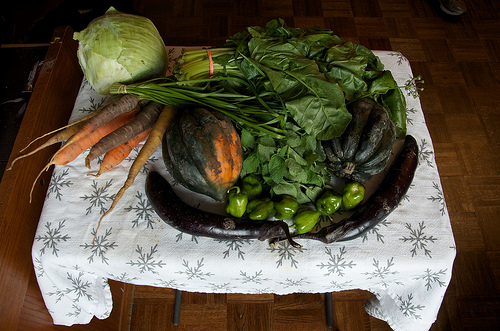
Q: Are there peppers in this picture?
A: Yes, there are peppers.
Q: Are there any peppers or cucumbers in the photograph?
A: Yes, there are peppers.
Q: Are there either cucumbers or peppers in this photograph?
A: Yes, there are peppers.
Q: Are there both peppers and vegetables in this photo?
A: Yes, there are both peppers and vegetables.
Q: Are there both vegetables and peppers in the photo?
A: Yes, there are both peppers and vegetables.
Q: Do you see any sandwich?
A: No, there are no sandwiches.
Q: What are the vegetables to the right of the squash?
A: The vegetables are peppers.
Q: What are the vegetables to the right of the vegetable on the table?
A: The vegetables are peppers.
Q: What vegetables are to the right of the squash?
A: The vegetables are peppers.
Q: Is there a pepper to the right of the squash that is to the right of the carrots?
A: Yes, there are peppers to the right of the squash.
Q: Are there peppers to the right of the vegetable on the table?
A: Yes, there are peppers to the right of the squash.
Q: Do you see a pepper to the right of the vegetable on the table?
A: Yes, there are peppers to the right of the squash.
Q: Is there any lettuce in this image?
A: Yes, there is lettuce.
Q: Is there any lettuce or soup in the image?
A: Yes, there is lettuce.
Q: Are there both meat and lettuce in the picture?
A: No, there is lettuce but no meat.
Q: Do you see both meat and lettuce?
A: No, there is lettuce but no meat.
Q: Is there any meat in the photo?
A: No, there is no meat.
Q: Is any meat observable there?
A: No, there is no meat.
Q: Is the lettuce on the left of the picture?
A: Yes, the lettuce is on the left of the image.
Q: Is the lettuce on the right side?
A: No, the lettuce is on the left of the image.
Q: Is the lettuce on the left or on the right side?
A: The lettuce is on the left of the image.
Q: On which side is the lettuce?
A: The lettuce is on the left of the image.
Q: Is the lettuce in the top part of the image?
A: Yes, the lettuce is in the top of the image.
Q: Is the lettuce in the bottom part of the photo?
A: No, the lettuce is in the top of the image.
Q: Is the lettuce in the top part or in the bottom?
A: The lettuce is in the top of the image.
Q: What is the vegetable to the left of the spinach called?
A: The vegetable is lettuce.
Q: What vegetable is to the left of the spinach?
A: The vegetable is lettuce.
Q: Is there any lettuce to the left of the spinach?
A: Yes, there is lettuce to the left of the spinach.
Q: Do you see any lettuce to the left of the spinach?
A: Yes, there is lettuce to the left of the spinach.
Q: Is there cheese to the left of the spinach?
A: No, there is lettuce to the left of the spinach.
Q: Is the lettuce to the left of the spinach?
A: Yes, the lettuce is to the left of the spinach.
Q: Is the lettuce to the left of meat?
A: No, the lettuce is to the left of the spinach.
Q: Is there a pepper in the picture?
A: Yes, there is a pepper.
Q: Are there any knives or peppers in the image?
A: Yes, there is a pepper.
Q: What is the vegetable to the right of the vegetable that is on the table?
A: The vegetable is a pepper.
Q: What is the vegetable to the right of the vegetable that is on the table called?
A: The vegetable is a pepper.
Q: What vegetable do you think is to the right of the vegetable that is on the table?
A: The vegetable is a pepper.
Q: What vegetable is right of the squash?
A: The vegetable is a pepper.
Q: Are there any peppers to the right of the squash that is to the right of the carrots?
A: Yes, there is a pepper to the right of the squash.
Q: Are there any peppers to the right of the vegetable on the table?
A: Yes, there is a pepper to the right of the squash.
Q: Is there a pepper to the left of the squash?
A: No, the pepper is to the right of the squash.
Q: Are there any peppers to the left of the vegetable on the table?
A: No, the pepper is to the right of the squash.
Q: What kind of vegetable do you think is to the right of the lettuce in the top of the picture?
A: The vegetable is spinach.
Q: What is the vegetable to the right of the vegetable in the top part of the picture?
A: The vegetable is spinach.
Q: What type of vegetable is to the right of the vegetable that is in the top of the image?
A: The vegetable is spinach.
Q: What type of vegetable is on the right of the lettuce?
A: The vegetable is spinach.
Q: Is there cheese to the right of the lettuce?
A: No, there is spinach to the right of the lettuce.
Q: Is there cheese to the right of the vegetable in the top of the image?
A: No, there is spinach to the right of the lettuce.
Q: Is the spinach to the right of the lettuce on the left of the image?
A: Yes, the spinach is to the right of the lettuce.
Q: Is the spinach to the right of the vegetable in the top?
A: Yes, the spinach is to the right of the lettuce.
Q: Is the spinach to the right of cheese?
A: No, the spinach is to the right of the lettuce.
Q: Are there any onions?
A: Yes, there is an onion.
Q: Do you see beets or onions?
A: Yes, there is an onion.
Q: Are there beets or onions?
A: Yes, there is an onion.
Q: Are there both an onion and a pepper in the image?
A: Yes, there are both an onion and a pepper.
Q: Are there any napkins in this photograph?
A: No, there are no napkins.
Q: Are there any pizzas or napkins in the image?
A: No, there are no napkins or pizzas.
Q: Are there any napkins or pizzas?
A: No, there are no napkins or pizzas.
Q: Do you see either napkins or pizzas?
A: No, there are no napkins or pizzas.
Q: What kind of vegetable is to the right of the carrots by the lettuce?
A: The vegetable is an onion.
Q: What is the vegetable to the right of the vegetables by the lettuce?
A: The vegetable is an onion.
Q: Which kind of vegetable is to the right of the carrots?
A: The vegetable is an onion.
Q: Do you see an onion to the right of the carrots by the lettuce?
A: Yes, there is an onion to the right of the carrots.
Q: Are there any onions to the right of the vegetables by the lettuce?
A: Yes, there is an onion to the right of the carrots.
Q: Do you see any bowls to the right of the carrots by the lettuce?
A: No, there is an onion to the right of the carrots.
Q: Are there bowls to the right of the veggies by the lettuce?
A: No, there is an onion to the right of the carrots.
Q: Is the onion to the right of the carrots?
A: Yes, the onion is to the right of the carrots.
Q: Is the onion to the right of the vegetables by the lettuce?
A: Yes, the onion is to the right of the carrots.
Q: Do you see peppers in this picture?
A: Yes, there is a pepper.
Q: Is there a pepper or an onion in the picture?
A: Yes, there is a pepper.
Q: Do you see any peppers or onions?
A: Yes, there is a pepper.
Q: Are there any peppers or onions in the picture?
A: Yes, there is a pepper.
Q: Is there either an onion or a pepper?
A: Yes, there is a pepper.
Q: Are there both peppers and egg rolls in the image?
A: No, there is a pepper but no egg rolls.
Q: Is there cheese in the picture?
A: No, there is no cheese.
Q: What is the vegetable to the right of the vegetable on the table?
A: The vegetable is a pepper.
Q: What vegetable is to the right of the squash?
A: The vegetable is a pepper.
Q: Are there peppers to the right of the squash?
A: Yes, there is a pepper to the right of the squash.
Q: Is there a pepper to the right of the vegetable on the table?
A: Yes, there is a pepper to the right of the squash.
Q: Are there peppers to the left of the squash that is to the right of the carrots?
A: No, the pepper is to the right of the squash.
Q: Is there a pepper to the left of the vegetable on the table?
A: No, the pepper is to the right of the squash.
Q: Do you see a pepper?
A: Yes, there is a pepper.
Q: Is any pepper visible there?
A: Yes, there is a pepper.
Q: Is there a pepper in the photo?
A: Yes, there is a pepper.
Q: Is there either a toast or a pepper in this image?
A: Yes, there is a pepper.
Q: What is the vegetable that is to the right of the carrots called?
A: The vegetable is a pepper.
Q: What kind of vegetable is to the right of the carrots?
A: The vegetable is a pepper.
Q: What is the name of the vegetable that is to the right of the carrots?
A: The vegetable is a pepper.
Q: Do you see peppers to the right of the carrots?
A: Yes, there is a pepper to the right of the carrots.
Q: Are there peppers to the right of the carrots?
A: Yes, there is a pepper to the right of the carrots.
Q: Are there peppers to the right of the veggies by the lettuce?
A: Yes, there is a pepper to the right of the carrots.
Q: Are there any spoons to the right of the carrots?
A: No, there is a pepper to the right of the carrots.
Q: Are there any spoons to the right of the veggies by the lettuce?
A: No, there is a pepper to the right of the carrots.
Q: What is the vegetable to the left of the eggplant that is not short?
A: The vegetable is a pepper.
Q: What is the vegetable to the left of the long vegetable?
A: The vegetable is a pepper.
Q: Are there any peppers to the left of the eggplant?
A: Yes, there is a pepper to the left of the eggplant.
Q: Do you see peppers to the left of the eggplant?
A: Yes, there is a pepper to the left of the eggplant.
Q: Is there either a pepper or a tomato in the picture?
A: Yes, there is a pepper.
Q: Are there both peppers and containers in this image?
A: No, there is a pepper but no containers.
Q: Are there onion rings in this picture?
A: No, there are no onion rings.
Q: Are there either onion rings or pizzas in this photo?
A: No, there are no onion rings or pizzas.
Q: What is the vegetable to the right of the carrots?
A: The vegetable is a pepper.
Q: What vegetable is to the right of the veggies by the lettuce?
A: The vegetable is a pepper.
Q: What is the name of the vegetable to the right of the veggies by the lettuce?
A: The vegetable is a pepper.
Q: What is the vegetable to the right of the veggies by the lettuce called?
A: The vegetable is a pepper.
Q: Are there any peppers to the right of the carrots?
A: Yes, there is a pepper to the right of the carrots.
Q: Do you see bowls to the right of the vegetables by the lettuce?
A: No, there is a pepper to the right of the carrots.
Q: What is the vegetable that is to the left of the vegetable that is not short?
A: The vegetable is a pepper.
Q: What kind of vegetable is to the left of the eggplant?
A: The vegetable is a pepper.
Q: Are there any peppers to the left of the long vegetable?
A: Yes, there is a pepper to the left of the eggplant.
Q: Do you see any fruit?
A: Yes, there is a fruit.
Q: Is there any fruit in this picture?
A: Yes, there is a fruit.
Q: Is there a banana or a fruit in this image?
A: Yes, there is a fruit.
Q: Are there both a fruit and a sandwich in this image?
A: No, there is a fruit but no sandwiches.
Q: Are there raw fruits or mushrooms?
A: Yes, there is a raw fruit.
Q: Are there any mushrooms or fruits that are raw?
A: Yes, the fruit is raw.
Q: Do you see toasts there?
A: No, there are no toasts.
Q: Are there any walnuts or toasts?
A: No, there are no toasts or walnuts.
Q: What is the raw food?
A: The food is a fruit.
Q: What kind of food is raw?
A: The food is a fruit.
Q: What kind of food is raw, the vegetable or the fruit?
A: The fruit is raw.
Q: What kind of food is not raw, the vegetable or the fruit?
A: The vegetable is not raw.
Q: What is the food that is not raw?
A: The food is a vegetable.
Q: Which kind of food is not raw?
A: The food is a vegetable.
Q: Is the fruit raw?
A: Yes, the fruit is raw.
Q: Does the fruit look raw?
A: Yes, the fruit is raw.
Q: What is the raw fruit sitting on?
A: The fruit is sitting on the table.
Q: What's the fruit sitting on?
A: The fruit is sitting on the table.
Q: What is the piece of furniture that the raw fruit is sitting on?
A: The piece of furniture is a table.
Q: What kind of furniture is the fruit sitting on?
A: The fruit is sitting on the table.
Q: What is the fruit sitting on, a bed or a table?
A: The fruit is sitting on a table.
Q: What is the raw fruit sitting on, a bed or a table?
A: The fruit is sitting on a table.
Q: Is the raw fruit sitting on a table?
A: Yes, the fruit is sitting on a table.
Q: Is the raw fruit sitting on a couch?
A: No, the fruit is sitting on a table.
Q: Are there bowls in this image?
A: No, there are no bowls.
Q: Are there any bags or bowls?
A: No, there are no bowls or bags.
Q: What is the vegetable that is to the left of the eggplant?
A: The vegetable is a squash.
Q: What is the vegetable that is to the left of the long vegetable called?
A: The vegetable is a squash.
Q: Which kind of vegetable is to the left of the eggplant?
A: The vegetable is a squash.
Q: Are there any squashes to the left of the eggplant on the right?
A: Yes, there is a squash to the left of the eggplant.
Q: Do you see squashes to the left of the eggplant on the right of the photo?
A: Yes, there is a squash to the left of the eggplant.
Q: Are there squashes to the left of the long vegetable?
A: Yes, there is a squash to the left of the eggplant.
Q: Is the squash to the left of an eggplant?
A: Yes, the squash is to the left of an eggplant.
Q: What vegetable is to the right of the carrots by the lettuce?
A: The vegetable is a squash.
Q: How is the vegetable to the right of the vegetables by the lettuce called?
A: The vegetable is a squash.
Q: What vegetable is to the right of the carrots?
A: The vegetable is a squash.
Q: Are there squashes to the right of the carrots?
A: Yes, there is a squash to the right of the carrots.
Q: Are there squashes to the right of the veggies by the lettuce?
A: Yes, there is a squash to the right of the carrots.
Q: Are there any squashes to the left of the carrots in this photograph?
A: No, the squash is to the right of the carrots.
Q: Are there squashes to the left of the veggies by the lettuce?
A: No, the squash is to the right of the carrots.